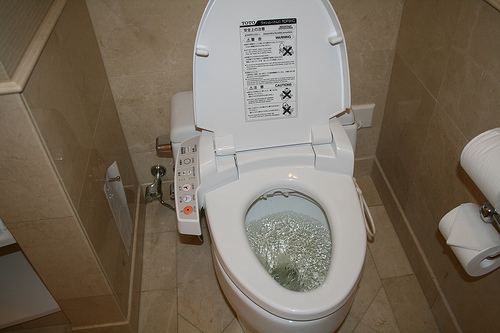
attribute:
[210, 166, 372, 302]
toilet bowl — white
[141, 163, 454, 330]
floor — tiles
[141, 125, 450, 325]
tiles — brown, ceramic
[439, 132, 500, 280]
tissue paper — here, roll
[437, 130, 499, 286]
paper — white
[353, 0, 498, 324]
wall — here, tiled, brown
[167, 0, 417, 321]
toilet — here, flushed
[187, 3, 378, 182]
lid — open, here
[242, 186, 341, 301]
toilet sink — here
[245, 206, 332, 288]
water — inside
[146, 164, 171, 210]
pipe — here, metallic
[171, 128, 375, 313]
bowl — hi tech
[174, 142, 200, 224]
controls — electronic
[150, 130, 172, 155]
control — manual, toilet's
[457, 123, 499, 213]
toilet paper — roll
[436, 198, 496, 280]
toilet paper — roll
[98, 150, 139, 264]
bag — napkin disposal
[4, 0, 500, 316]
tiles — ceramic, brown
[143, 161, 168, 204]
water valve — regulating flow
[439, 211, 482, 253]
end — shaped